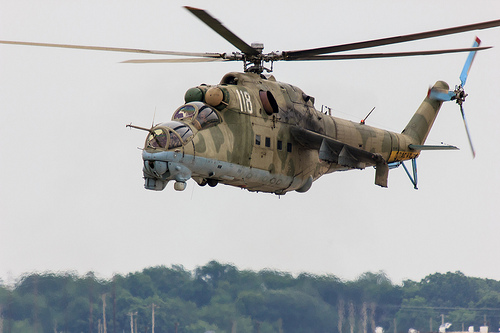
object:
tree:
[197, 294, 246, 330]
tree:
[473, 288, 498, 331]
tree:
[363, 270, 387, 332]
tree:
[143, 292, 165, 331]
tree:
[37, 275, 82, 331]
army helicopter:
[0, 4, 499, 196]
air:
[2, 1, 495, 278]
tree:
[223, 280, 300, 331]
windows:
[274, 139, 283, 151]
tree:
[85, 279, 122, 331]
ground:
[0, 325, 493, 332]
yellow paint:
[389, 151, 420, 162]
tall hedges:
[242, 295, 285, 332]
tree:
[367, 281, 407, 331]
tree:
[421, 277, 439, 332]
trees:
[449, 305, 477, 330]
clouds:
[0, 3, 500, 292]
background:
[1, 263, 498, 331]